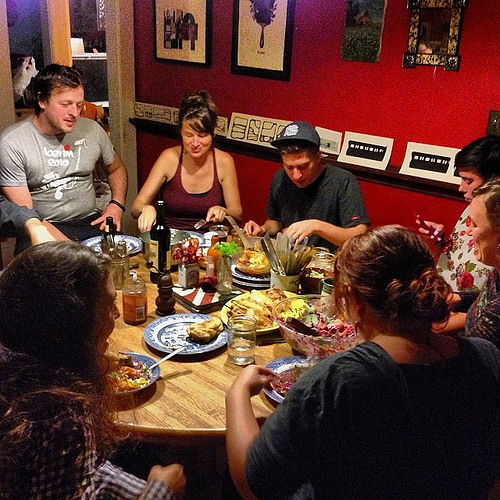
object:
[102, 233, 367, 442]
table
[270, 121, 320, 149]
ball cap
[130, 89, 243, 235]
woman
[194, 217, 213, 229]
fork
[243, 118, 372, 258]
man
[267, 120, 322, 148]
hat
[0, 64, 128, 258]
man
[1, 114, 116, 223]
t shirt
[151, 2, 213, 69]
frames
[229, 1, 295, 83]
frames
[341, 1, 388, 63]
frames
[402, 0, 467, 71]
frames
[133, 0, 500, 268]
wall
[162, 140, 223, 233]
top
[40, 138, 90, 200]
surfboard